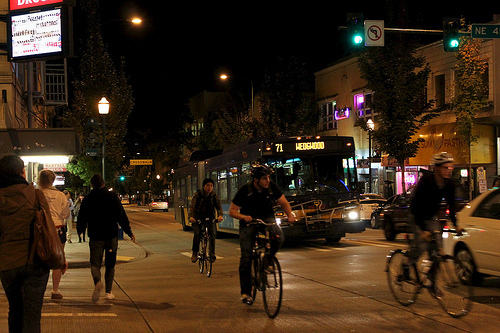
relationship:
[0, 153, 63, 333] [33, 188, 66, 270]
people carrying bag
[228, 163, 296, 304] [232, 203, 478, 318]
man riding bicylce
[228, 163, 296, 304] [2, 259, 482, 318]
man walking across street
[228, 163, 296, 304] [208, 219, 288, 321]
man riding bike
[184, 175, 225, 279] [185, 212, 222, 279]
man riding bike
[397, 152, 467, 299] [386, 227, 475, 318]
man riding bike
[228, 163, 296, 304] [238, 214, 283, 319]
man riding bike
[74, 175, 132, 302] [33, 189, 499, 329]
people crossing street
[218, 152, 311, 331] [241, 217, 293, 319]
man riding bicylce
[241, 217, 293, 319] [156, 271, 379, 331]
bicylce on street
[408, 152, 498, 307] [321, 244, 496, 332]
car on street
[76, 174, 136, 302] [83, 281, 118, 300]
people wearing shoes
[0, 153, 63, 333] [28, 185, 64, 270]
people carrying bag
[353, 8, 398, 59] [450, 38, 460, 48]
sign next to green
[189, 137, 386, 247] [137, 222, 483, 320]
bus on street